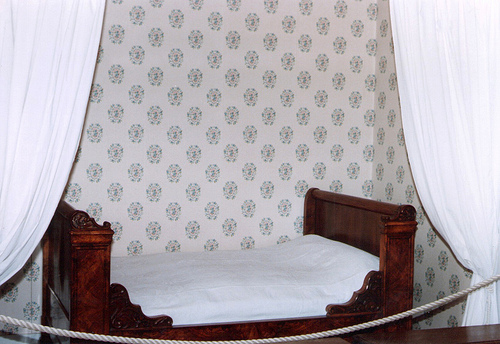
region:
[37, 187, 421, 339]
a small wooden bed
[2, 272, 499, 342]
a twisted rope cordons off a small bed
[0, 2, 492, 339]
off white and green patterned wallpaper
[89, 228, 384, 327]
a white sheet on a small bed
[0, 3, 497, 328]
white drapes in front of a wooden bed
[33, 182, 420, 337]
fancy carving on an old wooden bed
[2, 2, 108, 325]
a white curtain is tied back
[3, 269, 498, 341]
a pale grey rope makes the bed inaccessible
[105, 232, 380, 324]
a white sheet is creased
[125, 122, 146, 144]
circular design on some wallpaper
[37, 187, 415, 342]
the wood furniture on display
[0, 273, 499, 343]
the rope in front of the furniture piece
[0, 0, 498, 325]
the white curtains hanging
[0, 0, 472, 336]
the patterned wall paper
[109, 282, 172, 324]
the decorative wooden piece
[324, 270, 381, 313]
the decorative wooden piece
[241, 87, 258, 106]
the pattern on the wall paper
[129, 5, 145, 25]
the pattern on the wall paper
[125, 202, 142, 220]
the pattern on the wall paper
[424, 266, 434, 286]
the pattern on the wall paper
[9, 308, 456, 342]
it is a long rope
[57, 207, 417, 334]
it is a small bed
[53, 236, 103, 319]
bed cot color is brown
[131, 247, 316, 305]
bed color is white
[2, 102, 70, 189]
it is a screen cloth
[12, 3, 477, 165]
screen cloth color is white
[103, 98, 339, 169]
it is a flower wall designs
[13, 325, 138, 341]
it is a white color roap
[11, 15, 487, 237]
two screen cloth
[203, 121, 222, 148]
it is a wall design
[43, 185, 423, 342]
dark wood bed frame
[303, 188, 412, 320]
headboard of the bed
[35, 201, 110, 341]
footboard of the bed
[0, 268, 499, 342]
white rope in front of bed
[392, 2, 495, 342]
white curtain hanging on the right side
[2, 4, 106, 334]
white curtain hanging on right side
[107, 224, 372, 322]
white sheets on the bed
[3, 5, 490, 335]
patterned wallpaper on the walls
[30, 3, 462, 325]
white background of wallpaper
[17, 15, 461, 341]
black design on white wallpaper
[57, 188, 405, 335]
wooden furniture behind a rope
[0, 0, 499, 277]
white curtains pulled back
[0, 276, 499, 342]
white rope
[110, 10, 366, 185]
patterned wallpaper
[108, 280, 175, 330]
carved woodwork on the furniture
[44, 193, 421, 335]
furniture on display behind a rope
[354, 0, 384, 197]
corner of the wall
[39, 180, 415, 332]
small wooden bed with a white mattress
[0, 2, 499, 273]
white curtains behind a rope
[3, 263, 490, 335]
rope hanging in front of a display